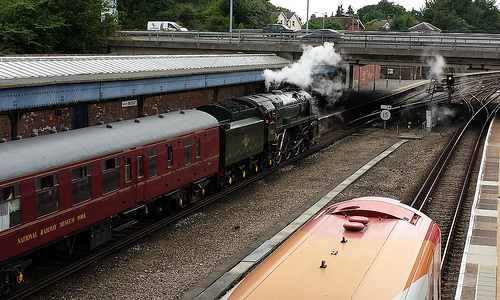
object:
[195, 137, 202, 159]
window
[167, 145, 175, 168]
window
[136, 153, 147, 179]
window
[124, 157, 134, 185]
window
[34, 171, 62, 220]
window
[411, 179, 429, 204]
tracks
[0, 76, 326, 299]
train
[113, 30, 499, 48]
road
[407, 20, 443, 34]
buildings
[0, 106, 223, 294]
train car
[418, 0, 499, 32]
tree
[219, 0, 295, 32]
tree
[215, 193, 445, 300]
train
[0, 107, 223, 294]
car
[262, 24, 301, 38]
black suv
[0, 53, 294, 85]
roof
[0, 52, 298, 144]
building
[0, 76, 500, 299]
ground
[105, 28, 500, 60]
bridge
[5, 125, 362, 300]
train track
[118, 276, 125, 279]
pebbles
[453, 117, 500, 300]
platform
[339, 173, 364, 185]
slats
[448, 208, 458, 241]
tracks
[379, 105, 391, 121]
sign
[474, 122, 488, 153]
tracks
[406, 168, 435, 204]
tracks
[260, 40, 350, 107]
smoke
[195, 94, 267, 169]
coal car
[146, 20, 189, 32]
van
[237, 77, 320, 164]
engine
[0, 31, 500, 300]
railway station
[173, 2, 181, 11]
trees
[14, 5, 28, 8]
branches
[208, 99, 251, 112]
coal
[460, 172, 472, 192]
tracks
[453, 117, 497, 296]
edge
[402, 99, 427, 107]
tracks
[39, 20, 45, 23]
leaves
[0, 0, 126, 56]
tree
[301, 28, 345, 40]
car